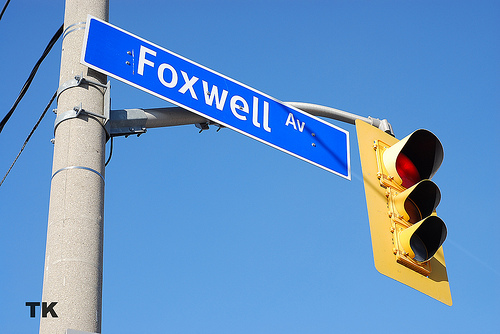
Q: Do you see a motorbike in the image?
A: No, there are no motorcycles.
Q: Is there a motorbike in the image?
A: No, there are no motorcycles.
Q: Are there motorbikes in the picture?
A: No, there are no motorbikes.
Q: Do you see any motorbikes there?
A: No, there are no motorbikes.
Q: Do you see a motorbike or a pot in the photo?
A: No, there are no motorcycles or pots.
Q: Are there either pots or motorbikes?
A: No, there are no motorbikes or pots.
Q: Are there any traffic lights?
A: Yes, there is a traffic light.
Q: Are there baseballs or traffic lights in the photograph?
A: Yes, there is a traffic light.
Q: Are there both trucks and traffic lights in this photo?
A: No, there is a traffic light but no trucks.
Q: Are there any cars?
A: No, there are no cars.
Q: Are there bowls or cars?
A: No, there are no cars or bowls.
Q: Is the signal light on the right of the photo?
A: Yes, the signal light is on the right of the image.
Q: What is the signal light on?
A: The signal light is on the pole.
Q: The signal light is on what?
A: The signal light is on the pole.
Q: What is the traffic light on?
A: The signal light is on the pole.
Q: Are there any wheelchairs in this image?
A: No, there are no wheelchairs.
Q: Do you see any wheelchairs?
A: No, there are no wheelchairs.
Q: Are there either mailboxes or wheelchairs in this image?
A: No, there are no wheelchairs or mailboxes.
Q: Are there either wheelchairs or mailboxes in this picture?
A: No, there are no wheelchairs or mailboxes.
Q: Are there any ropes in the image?
A: No, there are no ropes.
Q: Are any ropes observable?
A: No, there are no ropes.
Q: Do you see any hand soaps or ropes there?
A: No, there are no ropes or hand soaps.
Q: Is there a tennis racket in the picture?
A: No, there are no rackets.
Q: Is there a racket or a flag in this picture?
A: No, there are no rackets or flags.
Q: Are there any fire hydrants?
A: No, there are no fire hydrants.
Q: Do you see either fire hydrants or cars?
A: No, there are no fire hydrants or cars.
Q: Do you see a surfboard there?
A: No, there are no surfboards.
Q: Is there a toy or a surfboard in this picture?
A: No, there are no surfboards or toys.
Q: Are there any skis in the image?
A: No, there are no skis.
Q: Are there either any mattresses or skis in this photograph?
A: No, there are no skis or mattresses.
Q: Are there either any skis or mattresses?
A: No, there are no skis or mattresses.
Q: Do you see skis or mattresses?
A: No, there are no skis or mattresses.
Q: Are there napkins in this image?
A: No, there are no napkins.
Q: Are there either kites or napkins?
A: No, there are no napkins or kites.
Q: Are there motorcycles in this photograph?
A: No, there are no motorcycles.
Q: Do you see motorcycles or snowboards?
A: No, there are no motorcycles or snowboards.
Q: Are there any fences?
A: No, there are no fences.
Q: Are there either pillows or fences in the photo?
A: No, there are no fences or pillows.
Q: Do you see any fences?
A: No, there are no fences.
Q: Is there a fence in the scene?
A: No, there are no fences.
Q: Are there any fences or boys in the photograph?
A: No, there are no fences or boys.